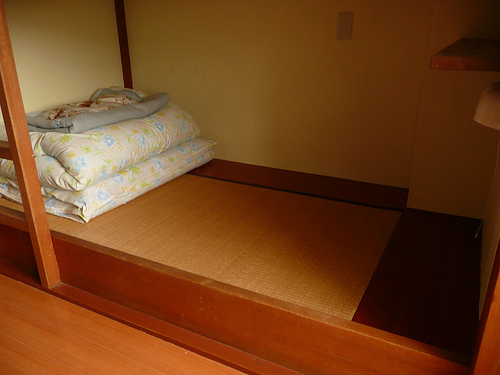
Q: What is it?
A: A bed.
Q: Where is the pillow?
A: On the bed.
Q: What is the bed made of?
A: Wood.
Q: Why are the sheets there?
A: To make bed.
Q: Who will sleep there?
A: People.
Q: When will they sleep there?
A: Soon.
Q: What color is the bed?
A: Brown.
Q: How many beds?
A: 1.